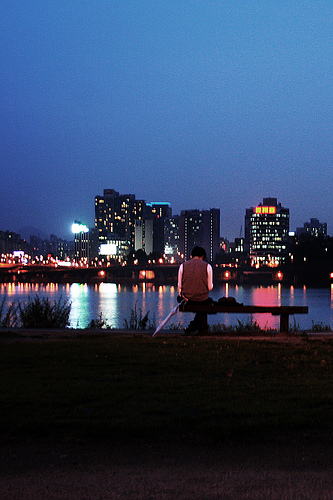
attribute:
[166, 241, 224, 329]
man — sitting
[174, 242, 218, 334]
man — lonely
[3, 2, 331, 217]
sky — dark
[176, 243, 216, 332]
boy — small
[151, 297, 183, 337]
toy sword — silver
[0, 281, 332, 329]
water — reflective, calm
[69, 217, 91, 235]
lights — bright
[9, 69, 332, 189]
sky — blue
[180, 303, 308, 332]
bench — park bench, to sit on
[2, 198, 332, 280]
lights — bright, pretty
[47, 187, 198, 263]
lights — on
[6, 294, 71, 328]
foliage — green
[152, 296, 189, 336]
umbrella — light-colored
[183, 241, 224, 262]
head — bent forward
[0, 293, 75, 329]
shrubs — green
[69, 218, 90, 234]
sign — glowing, blue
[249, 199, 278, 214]
windows — lit up